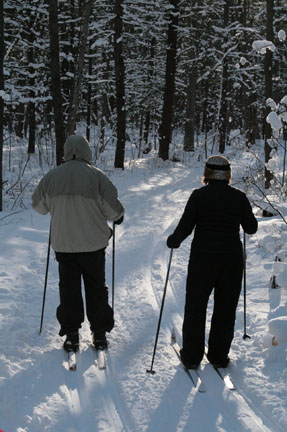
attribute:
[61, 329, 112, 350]
feet — black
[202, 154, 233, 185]
hat — white, black, gray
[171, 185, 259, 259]
jacket — black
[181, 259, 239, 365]
pants — black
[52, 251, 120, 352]
pants — black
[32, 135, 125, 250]
jacket — grey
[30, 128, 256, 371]
people — skiing, standing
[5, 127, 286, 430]
snow — lit, covering, white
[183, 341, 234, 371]
boots — black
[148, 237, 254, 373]
poles — standing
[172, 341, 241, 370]
feet — person's